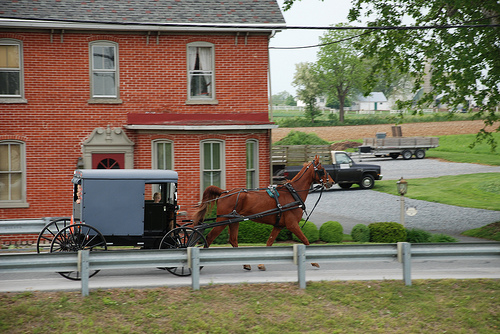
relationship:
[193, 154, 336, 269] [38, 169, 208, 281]
horse pulls buggy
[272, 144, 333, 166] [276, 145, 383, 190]
wood on truck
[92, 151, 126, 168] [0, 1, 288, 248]
door of building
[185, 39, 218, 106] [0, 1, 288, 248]
window of building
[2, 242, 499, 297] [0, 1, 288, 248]
rail near building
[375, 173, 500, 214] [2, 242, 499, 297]
grass near road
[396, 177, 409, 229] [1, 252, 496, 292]
light near road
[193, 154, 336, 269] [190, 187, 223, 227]
horse has tail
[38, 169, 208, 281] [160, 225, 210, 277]
buggy has wheel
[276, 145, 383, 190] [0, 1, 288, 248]
truck near building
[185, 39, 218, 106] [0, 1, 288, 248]
window on building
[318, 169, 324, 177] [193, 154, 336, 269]
blinder on horse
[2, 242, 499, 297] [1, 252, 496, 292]
rail near road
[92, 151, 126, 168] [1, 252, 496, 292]
door near road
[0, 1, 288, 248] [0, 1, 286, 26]
building has roof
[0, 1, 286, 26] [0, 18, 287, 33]
roof has gutter